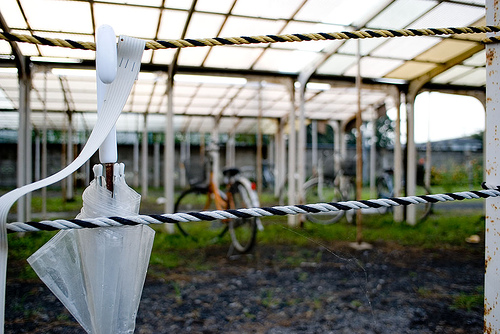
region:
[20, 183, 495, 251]
white and black rope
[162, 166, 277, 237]
bicycle in background on grass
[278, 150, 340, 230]
bicycle in background on grass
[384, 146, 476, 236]
bicycle in background on grass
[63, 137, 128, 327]
white umbrella on ropes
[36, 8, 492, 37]
yellow and black rope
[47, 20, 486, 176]
glass roof overhead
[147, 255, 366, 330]
dirt on ground by bikes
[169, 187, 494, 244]
grass growing on ground by bikes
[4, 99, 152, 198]
white tag by umbrella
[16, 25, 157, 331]
a white umbrella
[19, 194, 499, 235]
a black and white rope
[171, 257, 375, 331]
gray and black gravel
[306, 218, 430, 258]
green grass on the ground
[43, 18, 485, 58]
a yellow and black rope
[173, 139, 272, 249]
a orange and silver bike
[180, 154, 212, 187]
a basket on a bike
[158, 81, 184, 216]
a white wooden pole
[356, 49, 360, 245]
a rusty white pole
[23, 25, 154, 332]
clear umbrella hanging from rope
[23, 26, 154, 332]
white and clear umbrella closed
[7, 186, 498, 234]
white and black rope hanging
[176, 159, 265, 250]
bicycle in background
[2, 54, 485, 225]
poles holding structure up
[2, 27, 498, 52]
weathered rope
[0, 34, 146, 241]
white strap around rope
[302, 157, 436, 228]
two bicycles in background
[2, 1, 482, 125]
glass or plastic see through ceiling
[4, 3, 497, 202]
outside structure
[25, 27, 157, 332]
white umbrella hanging on a rope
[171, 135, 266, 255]
blurry orange bicycle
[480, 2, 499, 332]
rusty white pole on right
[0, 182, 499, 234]
black and white horizontal rope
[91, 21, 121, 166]
white plastic umbrella handle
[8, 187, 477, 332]
ground with dirty and green grass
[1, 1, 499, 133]
roof with white panels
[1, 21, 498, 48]
dirty black and white rope on top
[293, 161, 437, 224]
blurry bicycle with black tires to the right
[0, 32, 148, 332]
white plastic strap hanging from rope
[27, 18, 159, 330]
clear umbrella on a rope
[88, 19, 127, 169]
white handle of an umbrella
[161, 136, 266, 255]
orange bike on the grass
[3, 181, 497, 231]
black and white rope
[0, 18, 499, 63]
yellow and black rope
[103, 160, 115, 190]
rusted metal part of an umbrella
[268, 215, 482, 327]
spider web under the black and white rope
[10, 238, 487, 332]
area of dirt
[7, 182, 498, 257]
green grassy area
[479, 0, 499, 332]
white rusty pole attached to ropes